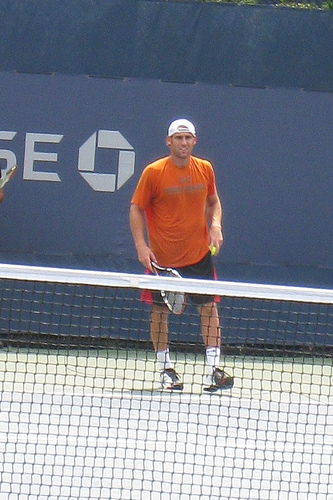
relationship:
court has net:
[4, 347, 332, 498] [2, 262, 331, 492]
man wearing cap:
[126, 117, 236, 399] [164, 115, 201, 141]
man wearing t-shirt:
[126, 117, 236, 399] [128, 154, 219, 272]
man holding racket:
[126, 117, 236, 399] [147, 259, 190, 322]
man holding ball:
[126, 117, 236, 399] [206, 241, 221, 259]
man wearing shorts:
[126, 117, 236, 399] [133, 248, 223, 309]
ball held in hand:
[206, 241, 221, 259] [208, 220, 226, 254]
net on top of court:
[2, 262, 331, 492] [4, 347, 332, 498]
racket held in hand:
[147, 259, 190, 322] [130, 239, 159, 273]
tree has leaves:
[202, 1, 332, 14] [202, 2, 332, 14]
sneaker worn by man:
[156, 362, 187, 396] [126, 117, 236, 399]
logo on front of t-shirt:
[156, 173, 208, 211] [128, 154, 219, 272]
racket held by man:
[147, 259, 190, 322] [126, 117, 236, 399]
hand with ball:
[208, 220, 226, 254] [206, 241, 221, 259]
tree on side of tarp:
[202, 1, 332, 14] [3, 1, 331, 353]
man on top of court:
[126, 117, 236, 399] [4, 347, 332, 498]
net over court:
[2, 262, 331, 492] [4, 347, 332, 498]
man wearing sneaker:
[126, 117, 236, 399] [156, 362, 187, 396]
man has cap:
[126, 117, 236, 399] [164, 115, 201, 141]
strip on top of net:
[2, 260, 332, 318] [2, 262, 331, 492]